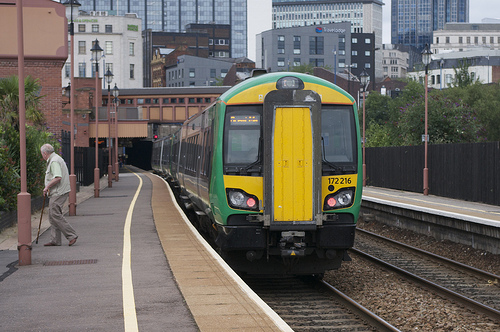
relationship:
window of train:
[226, 106, 259, 166] [143, 65, 372, 274]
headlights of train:
[226, 190, 354, 211] [129, 72, 372, 302]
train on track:
[151, 70, 363, 282] [242, 227, 500, 332]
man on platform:
[13, 119, 110, 256] [91, 102, 241, 324]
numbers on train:
[323, 176, 354, 184] [148, 68, 363, 288]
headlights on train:
[221, 170, 388, 228] [178, 64, 377, 295]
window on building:
[62, 40, 164, 91] [60, 13, 153, 86]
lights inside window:
[231, 113, 260, 125] [226, 106, 259, 166]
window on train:
[226, 106, 259, 166] [148, 68, 363, 288]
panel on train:
[269, 100, 316, 219] [205, 58, 366, 270]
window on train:
[293, 107, 397, 195] [157, 76, 428, 307]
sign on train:
[274, 75, 304, 91] [151, 70, 363, 282]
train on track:
[148, 68, 363, 288] [255, 241, 498, 319]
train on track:
[148, 68, 363, 288] [252, 198, 498, 330]